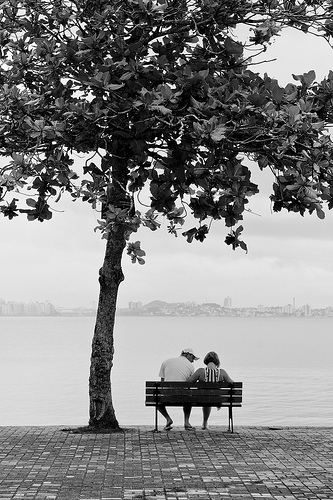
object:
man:
[157, 347, 198, 430]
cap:
[181, 348, 198, 358]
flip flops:
[163, 426, 173, 430]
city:
[0, 297, 333, 317]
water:
[1, 318, 332, 430]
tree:
[0, 0, 333, 428]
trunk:
[86, 135, 127, 433]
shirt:
[201, 368, 226, 383]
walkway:
[0, 429, 333, 498]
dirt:
[64, 426, 128, 434]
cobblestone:
[0, 428, 332, 496]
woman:
[188, 350, 235, 429]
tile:
[44, 479, 52, 485]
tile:
[110, 451, 117, 454]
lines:
[204, 367, 208, 383]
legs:
[183, 405, 192, 429]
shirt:
[159, 356, 195, 381]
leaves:
[0, 0, 74, 221]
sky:
[0, 0, 333, 308]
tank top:
[199, 363, 227, 388]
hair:
[203, 351, 220, 366]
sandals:
[163, 426, 174, 431]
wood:
[145, 380, 243, 407]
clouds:
[253, 229, 331, 303]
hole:
[70, 423, 133, 433]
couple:
[159, 347, 234, 429]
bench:
[145, 381, 243, 407]